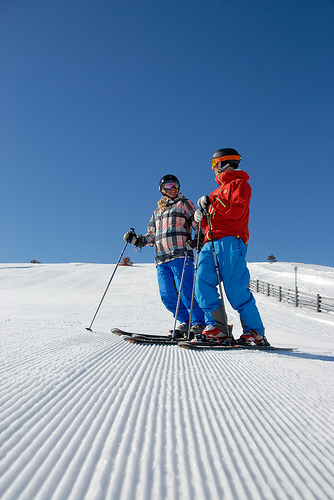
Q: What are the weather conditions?
A: It is cloudless.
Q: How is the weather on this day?
A: It is cloudless.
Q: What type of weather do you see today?
A: It is cloudless.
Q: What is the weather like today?
A: It is cloudless.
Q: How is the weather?
A: It is cloudless.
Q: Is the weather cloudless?
A: Yes, it is cloudless.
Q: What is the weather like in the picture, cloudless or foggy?
A: It is cloudless.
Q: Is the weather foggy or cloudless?
A: It is cloudless.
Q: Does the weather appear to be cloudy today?
A: No, it is cloudless.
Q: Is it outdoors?
A: Yes, it is outdoors.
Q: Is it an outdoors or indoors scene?
A: It is outdoors.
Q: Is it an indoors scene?
A: No, it is outdoors.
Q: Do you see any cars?
A: No, there are no cars.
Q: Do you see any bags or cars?
A: No, there are no cars or bags.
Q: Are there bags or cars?
A: No, there are no cars or bags.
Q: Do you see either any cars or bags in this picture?
A: No, there are no cars or bags.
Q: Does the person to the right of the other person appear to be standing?
A: Yes, the person is standing.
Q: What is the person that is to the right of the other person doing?
A: The person is standing.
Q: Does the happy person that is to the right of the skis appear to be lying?
A: No, the person is standing.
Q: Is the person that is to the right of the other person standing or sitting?
A: The person is standing.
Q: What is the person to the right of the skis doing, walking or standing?
A: The person is standing.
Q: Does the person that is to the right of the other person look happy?
A: Yes, the person is happy.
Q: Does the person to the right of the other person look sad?
A: No, the person is happy.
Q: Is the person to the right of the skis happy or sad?
A: The person is happy.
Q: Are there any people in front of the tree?
A: Yes, there is a person in front of the tree.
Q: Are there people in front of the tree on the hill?
A: Yes, there is a person in front of the tree.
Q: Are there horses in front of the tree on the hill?
A: No, there is a person in front of the tree.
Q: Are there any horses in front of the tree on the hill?
A: No, there is a person in front of the tree.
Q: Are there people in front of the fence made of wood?
A: Yes, there is a person in front of the fence.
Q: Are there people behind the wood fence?
A: No, the person is in front of the fence.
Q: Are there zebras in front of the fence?
A: No, there is a person in front of the fence.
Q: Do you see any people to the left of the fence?
A: Yes, there is a person to the left of the fence.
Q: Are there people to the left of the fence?
A: Yes, there is a person to the left of the fence.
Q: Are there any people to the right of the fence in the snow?
A: No, the person is to the left of the fence.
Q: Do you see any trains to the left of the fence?
A: No, there is a person to the left of the fence.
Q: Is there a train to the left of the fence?
A: No, there is a person to the left of the fence.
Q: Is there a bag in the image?
A: No, there are no bags.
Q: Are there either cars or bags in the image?
A: No, there are no bags or cars.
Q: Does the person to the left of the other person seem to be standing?
A: Yes, the person is standing.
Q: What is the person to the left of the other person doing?
A: The person is standing.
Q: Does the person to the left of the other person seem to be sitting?
A: No, the person is standing.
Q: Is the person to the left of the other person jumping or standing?
A: The person is standing.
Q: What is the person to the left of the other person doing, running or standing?
A: The person is standing.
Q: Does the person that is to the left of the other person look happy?
A: Yes, the person is happy.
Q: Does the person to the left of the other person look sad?
A: No, the person is happy.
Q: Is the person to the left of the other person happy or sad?
A: The person is happy.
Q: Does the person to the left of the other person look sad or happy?
A: The person is happy.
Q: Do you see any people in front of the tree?
A: Yes, there is a person in front of the tree.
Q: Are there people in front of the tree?
A: Yes, there is a person in front of the tree.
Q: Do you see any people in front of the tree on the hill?
A: Yes, there is a person in front of the tree.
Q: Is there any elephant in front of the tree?
A: No, there is a person in front of the tree.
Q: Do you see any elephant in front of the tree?
A: No, there is a person in front of the tree.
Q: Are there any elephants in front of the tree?
A: No, there is a person in front of the tree.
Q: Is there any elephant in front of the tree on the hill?
A: No, there is a person in front of the tree.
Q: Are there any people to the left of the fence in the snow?
A: Yes, there is a person to the left of the fence.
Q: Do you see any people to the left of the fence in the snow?
A: Yes, there is a person to the left of the fence.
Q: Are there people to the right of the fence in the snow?
A: No, the person is to the left of the fence.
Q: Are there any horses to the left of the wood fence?
A: No, there is a person to the left of the fence.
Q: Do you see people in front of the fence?
A: Yes, there is a person in front of the fence.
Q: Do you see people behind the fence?
A: No, the person is in front of the fence.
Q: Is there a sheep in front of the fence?
A: No, there is a person in front of the fence.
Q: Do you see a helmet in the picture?
A: Yes, there is a helmet.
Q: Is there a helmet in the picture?
A: Yes, there is a helmet.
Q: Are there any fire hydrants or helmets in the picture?
A: Yes, there is a helmet.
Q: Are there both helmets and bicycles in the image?
A: No, there is a helmet but no bikes.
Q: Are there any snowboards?
A: No, there are no snowboards.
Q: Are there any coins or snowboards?
A: No, there are no snowboards or coins.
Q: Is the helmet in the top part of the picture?
A: Yes, the helmet is in the top of the image.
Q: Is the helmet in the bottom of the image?
A: No, the helmet is in the top of the image.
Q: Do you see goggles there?
A: Yes, there are goggles.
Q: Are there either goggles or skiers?
A: Yes, there are goggles.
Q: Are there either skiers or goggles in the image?
A: Yes, there are goggles.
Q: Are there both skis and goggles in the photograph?
A: Yes, there are both goggles and skis.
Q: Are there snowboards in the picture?
A: No, there are no snowboards.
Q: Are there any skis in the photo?
A: Yes, there are skis.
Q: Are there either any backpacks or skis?
A: Yes, there are skis.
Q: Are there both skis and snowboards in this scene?
A: No, there are skis but no snowboards.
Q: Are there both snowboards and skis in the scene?
A: No, there are skis but no snowboards.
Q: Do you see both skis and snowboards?
A: No, there are skis but no snowboards.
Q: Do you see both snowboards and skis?
A: No, there are skis but no snowboards.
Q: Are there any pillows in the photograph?
A: No, there are no pillows.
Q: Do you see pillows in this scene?
A: No, there are no pillows.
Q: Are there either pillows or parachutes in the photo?
A: No, there are no pillows or parachutes.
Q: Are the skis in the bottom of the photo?
A: Yes, the skis are in the bottom of the image.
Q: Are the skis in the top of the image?
A: No, the skis are in the bottom of the image.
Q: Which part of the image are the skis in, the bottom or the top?
A: The skis are in the bottom of the image.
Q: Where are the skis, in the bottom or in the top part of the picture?
A: The skis are in the bottom of the image.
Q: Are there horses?
A: No, there are no horses.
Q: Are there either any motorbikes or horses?
A: No, there are no horses or motorbikes.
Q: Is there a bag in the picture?
A: No, there are no bags.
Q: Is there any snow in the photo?
A: Yes, there is snow.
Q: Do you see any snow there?
A: Yes, there is snow.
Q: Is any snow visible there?
A: Yes, there is snow.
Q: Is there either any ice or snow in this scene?
A: Yes, there is snow.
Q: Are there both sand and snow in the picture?
A: No, there is snow but no sand.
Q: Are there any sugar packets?
A: No, there are no sugar packets.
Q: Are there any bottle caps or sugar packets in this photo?
A: No, there are no sugar packets or bottle caps.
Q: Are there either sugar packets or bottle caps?
A: No, there are no sugar packets or bottle caps.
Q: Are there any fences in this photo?
A: Yes, there is a fence.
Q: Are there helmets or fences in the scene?
A: Yes, there is a fence.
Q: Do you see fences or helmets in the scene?
A: Yes, there is a fence.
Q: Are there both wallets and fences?
A: No, there is a fence but no wallets.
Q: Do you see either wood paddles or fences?
A: Yes, there is a wood fence.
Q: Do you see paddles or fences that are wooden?
A: Yes, the fence is wooden.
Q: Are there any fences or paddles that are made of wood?
A: Yes, the fence is made of wood.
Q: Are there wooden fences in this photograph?
A: Yes, there is a wood fence.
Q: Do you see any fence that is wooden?
A: Yes, there is a fence that is wooden.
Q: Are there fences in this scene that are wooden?
A: Yes, there is a fence that is wooden.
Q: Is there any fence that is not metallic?
A: Yes, there is a wooden fence.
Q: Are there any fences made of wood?
A: Yes, there is a fence that is made of wood.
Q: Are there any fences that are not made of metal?
A: Yes, there is a fence that is made of wood.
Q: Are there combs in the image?
A: No, there are no combs.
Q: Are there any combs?
A: No, there are no combs.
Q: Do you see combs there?
A: No, there are no combs.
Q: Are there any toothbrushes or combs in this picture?
A: No, there are no combs or toothbrushes.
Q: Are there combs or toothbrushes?
A: No, there are no combs or toothbrushes.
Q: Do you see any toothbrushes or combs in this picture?
A: No, there are no combs or toothbrushes.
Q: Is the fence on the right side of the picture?
A: Yes, the fence is on the right of the image.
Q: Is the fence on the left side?
A: No, the fence is on the right of the image.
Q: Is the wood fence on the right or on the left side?
A: The fence is on the right of the image.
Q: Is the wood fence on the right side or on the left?
A: The fence is on the right of the image.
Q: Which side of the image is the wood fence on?
A: The fence is on the right of the image.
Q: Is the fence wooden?
A: Yes, the fence is wooden.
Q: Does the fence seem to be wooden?
A: Yes, the fence is wooden.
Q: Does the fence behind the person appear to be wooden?
A: Yes, the fence is wooden.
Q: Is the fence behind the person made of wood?
A: Yes, the fence is made of wood.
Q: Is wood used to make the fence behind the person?
A: Yes, the fence is made of wood.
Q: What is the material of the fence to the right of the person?
A: The fence is made of wood.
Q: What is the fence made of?
A: The fence is made of wood.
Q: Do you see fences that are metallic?
A: No, there is a fence but it is wooden.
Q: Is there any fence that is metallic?
A: No, there is a fence but it is wooden.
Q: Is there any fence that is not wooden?
A: No, there is a fence but it is wooden.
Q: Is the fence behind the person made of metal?
A: No, the fence is made of wood.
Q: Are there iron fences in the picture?
A: No, there is a fence but it is made of wood.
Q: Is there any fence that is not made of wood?
A: No, there is a fence but it is made of wood.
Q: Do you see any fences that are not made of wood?
A: No, there is a fence but it is made of wood.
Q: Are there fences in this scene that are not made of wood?
A: No, there is a fence but it is made of wood.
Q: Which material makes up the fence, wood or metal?
A: The fence is made of wood.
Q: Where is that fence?
A: The fence is in the snow.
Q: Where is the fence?
A: The fence is in the snow.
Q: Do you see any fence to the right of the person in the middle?
A: Yes, there is a fence to the right of the person.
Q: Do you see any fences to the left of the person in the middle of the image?
A: No, the fence is to the right of the person.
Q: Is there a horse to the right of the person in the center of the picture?
A: No, there is a fence to the right of the person.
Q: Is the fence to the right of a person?
A: Yes, the fence is to the right of a person.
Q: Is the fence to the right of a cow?
A: No, the fence is to the right of a person.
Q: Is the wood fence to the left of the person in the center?
A: No, the fence is to the right of the person.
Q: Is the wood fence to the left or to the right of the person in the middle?
A: The fence is to the right of the person.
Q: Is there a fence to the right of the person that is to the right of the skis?
A: Yes, there is a fence to the right of the person.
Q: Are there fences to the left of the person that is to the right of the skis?
A: No, the fence is to the right of the person.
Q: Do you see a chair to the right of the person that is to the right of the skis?
A: No, there is a fence to the right of the person.